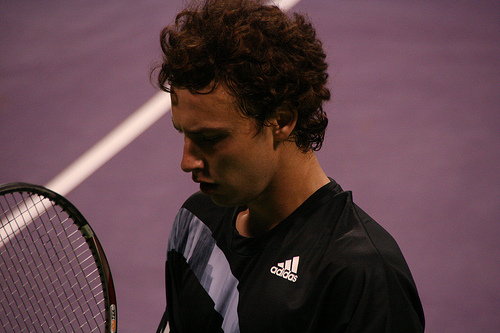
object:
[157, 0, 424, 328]
player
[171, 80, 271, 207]
face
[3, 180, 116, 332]
raquet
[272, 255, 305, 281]
logo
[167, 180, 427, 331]
shirt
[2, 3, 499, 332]
court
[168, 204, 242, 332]
stripe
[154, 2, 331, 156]
hair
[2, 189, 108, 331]
strings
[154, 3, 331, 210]
head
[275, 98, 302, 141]
ear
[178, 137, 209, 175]
nose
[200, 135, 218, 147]
eye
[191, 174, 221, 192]
mouth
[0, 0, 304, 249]
stripe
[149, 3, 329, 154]
perspiration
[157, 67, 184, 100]
curl